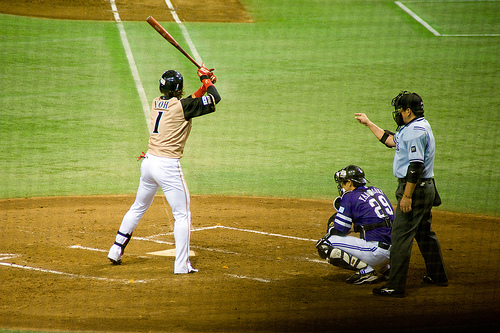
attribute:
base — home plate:
[144, 239, 204, 267]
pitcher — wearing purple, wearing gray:
[315, 162, 397, 284]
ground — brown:
[271, 241, 323, 283]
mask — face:
[330, 174, 355, 193]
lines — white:
[2, 223, 332, 284]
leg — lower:
[107, 150, 157, 263]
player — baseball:
[109, 62, 224, 277]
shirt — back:
[122, 88, 183, 147]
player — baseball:
[100, 64, 230, 281]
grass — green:
[284, 30, 346, 73]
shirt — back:
[391, 118, 437, 182]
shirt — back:
[331, 188, 393, 241]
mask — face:
[390, 88, 409, 124]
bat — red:
[144, 13, 217, 77]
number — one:
[367, 192, 393, 220]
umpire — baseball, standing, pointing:
[353, 90, 455, 299]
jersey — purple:
[332, 187, 393, 238]